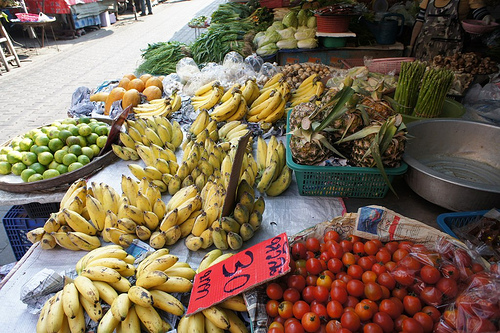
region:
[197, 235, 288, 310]
sign with a price on it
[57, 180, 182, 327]
bunches of bananas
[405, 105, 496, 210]
an empty aluminum pan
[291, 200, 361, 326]
tomatoes laid on top of newspaper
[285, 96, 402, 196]
pinapples in a plastic display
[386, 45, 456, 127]
two stalks of asparagus stood straight up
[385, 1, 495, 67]
woman carrying a pink bowl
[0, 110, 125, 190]
round tray of limes with a price card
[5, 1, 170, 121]
a narrow street running through the market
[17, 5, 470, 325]
varied display of fruits and vegetables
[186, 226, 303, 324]
red poster reads 30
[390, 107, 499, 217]
empty large metal container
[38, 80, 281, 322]
bananas on display for sale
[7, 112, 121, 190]
fruits on display for sale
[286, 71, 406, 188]
pineapples on display for sale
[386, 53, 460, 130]
vegetables on display for sale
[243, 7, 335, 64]
vegetables on display for sale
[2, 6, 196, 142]
street made of cobble stones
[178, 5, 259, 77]
vegetables on display for sale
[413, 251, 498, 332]
tomatoes wrapped in plastic bag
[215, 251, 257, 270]
The number 3 on the red sale sign.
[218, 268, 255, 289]
The number 0 on the red sale sign.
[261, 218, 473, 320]
The basket of tomatoes.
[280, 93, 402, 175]
The basket of pineapples.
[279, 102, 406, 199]
The green basket the pineapples are in.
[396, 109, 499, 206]
The silver bowl behind the basket of pineapples.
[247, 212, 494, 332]
The newspaper underneath the pile of tomatoes.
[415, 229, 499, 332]
The plastic wrap around some of the tomatoes.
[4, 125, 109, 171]
The pile of limes in front of the yellow bananas.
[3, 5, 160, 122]
The sidewalk in front of the stand with the fruits and vegetables.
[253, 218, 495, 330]
these are tomatoes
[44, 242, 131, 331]
a bunch of sweet bananas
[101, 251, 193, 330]
a bunch of sweet bananas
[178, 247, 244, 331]
a bunch of sweet bananas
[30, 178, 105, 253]
a bunch of sweet bananas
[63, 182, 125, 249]
a bunch of sweet bananas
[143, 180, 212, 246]
a bunch of sweet bananas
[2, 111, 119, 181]
these are lemons in the picture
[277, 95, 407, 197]
these are pineapples in a basket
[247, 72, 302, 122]
a bunch of sweet bananas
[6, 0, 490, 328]
an open market with stalls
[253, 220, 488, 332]
tomatoes piled on newspaper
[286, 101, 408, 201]
pineapples in a plastic basket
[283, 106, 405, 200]
the plastic basket is green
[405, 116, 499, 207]
an empty metal dish near the basket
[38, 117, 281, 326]
hands of yellow finger bananas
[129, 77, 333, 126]
rows of banana hands for sale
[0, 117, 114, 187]
a metal pan full of limes for sale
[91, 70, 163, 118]
the papayas are resting on plastic bags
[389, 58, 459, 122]
bunches of artichokes are standing upright